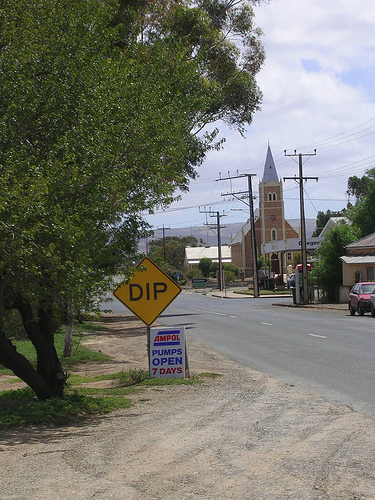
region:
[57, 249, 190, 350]
yellow road sign at entrance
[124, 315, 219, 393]
small gas station sign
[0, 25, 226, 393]
tree in foreground of picture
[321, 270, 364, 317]
red car parked on street side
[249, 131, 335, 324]
tall wooden cable pole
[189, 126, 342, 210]
many power cables in the air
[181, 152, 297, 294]
church in the background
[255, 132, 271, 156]
small cross on top of church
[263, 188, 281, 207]
two windows on church building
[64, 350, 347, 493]
dirt road next to street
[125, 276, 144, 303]
The letter D on the black and yellow sign.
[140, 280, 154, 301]
The letter I on the black and yellow sign.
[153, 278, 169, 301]
The letter P on the black and yellow sign.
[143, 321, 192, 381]
The white, blue and red sign next to the yellow and black sign.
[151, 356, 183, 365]
The word Open on the sign next to the black and yellow sign.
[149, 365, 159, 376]
The number 7 on the red, white and blue sign.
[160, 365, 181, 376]
The word Days on the red, white and blue sign.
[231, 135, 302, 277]
The church building on the right side of the street.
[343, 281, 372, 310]
The small red car parked on the right side of the street.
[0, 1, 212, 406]
The large tree next to the yellow and black sign.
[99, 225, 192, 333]
Yellow fourside road sign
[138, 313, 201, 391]
Red white and blue gas station sign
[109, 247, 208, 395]
Road sign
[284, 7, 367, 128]
White clouds in a blue sky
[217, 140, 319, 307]
Brick church with steeple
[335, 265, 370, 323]
Red parked car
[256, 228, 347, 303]
Gas station with overhang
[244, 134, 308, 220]
Brick church bell tower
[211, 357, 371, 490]
gravel driveway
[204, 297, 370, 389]
Blacktop road with white dotted lines in the center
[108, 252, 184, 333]
black and yellow street sign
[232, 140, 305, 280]
tall tan and brown brick church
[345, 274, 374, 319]
red a car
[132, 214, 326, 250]
hills in the distance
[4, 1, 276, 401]
large leafy green tree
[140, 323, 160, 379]
metal street sign pole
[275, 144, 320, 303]
tall wooden telephone pole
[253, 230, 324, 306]
small gas station with white covering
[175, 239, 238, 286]
house with a gray roof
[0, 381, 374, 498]
unpaved dirt drive way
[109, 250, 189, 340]
yellow sign with black word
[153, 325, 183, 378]
blue and red words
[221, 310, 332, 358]
white lines in road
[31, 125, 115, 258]
green leaves on tree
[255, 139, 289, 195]
steeple on top of church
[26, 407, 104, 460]
tree shadow on gravel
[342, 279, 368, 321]
red car on street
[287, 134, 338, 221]
telephone pole and wires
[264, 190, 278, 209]
arched windows on tower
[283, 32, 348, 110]
white clouds in daytime sky